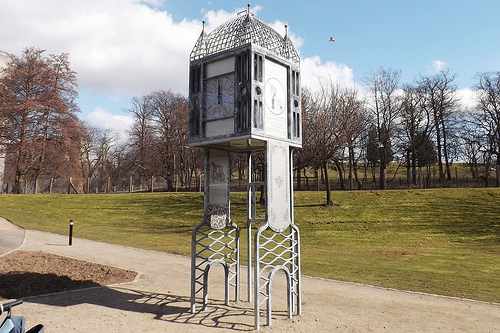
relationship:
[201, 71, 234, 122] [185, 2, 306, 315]
clock on stand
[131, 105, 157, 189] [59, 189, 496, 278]
tree behind field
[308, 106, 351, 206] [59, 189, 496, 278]
tree behind field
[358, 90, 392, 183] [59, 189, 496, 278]
tree behind field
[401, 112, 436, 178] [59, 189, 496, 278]
tree behind field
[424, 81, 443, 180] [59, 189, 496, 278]
tree behind field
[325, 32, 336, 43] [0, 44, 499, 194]
bird flies over trees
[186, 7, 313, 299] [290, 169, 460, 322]
clock tower in park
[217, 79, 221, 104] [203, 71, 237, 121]
hand on clock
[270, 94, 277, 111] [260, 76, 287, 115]
hands on clock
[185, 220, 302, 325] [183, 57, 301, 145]
metal base on clock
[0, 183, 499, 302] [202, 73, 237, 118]
lawn behind clock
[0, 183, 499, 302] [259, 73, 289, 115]
lawn behind clock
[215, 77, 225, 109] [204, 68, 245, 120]
hand of clock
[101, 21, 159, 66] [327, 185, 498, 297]
clouds above field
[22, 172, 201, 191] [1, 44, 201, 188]
fence near trees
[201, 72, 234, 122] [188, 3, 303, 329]
clock on clock tower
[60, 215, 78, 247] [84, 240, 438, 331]
black pole on path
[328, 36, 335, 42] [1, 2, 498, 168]
bird in sky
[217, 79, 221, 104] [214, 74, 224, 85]
hand of clock are on 12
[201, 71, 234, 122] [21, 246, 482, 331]
clock near concrete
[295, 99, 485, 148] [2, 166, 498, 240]
trees in field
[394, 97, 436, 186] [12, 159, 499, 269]
tree in field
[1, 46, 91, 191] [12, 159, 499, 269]
tree in field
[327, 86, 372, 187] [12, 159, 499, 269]
tree in field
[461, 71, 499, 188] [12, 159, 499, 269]
tree in field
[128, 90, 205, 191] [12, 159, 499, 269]
tree in field